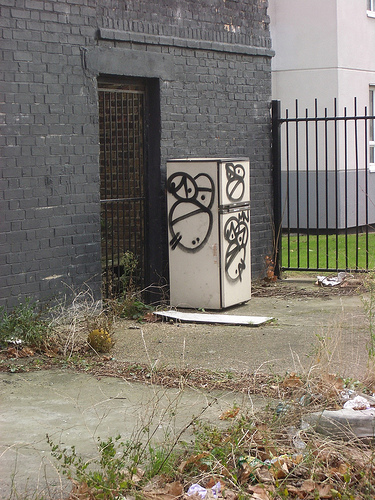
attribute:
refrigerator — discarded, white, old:
[161, 148, 259, 313]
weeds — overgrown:
[42, 271, 181, 367]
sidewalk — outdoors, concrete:
[3, 270, 374, 497]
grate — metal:
[97, 82, 157, 318]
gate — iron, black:
[268, 91, 374, 286]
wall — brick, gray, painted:
[2, 2, 276, 344]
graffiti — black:
[167, 157, 250, 287]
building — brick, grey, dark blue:
[2, 2, 289, 342]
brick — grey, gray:
[27, 81, 51, 97]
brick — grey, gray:
[48, 162, 69, 178]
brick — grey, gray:
[42, 20, 68, 37]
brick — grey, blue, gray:
[14, 17, 31, 36]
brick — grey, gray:
[4, 173, 25, 194]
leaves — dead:
[4, 343, 373, 499]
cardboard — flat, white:
[145, 296, 279, 337]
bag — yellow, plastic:
[302, 385, 375, 430]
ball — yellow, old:
[84, 318, 119, 356]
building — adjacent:
[269, 1, 373, 244]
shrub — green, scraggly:
[1, 298, 47, 356]